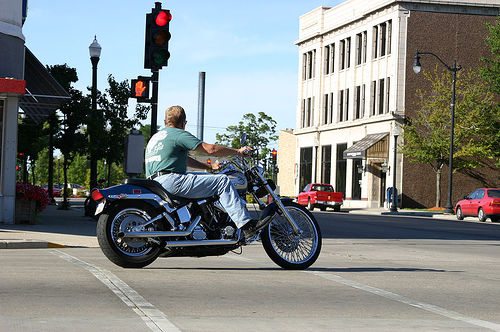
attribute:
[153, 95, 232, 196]
man — riding, without helmet, watching, driving, casting, out, enjoying, old, turned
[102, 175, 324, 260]
motorcycle — blue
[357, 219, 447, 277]
street — dark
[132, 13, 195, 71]
light — red, black, not on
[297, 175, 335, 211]
truck — red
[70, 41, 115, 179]
post — tall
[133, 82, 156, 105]
hand — up, symbol, orange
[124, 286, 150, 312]
line — white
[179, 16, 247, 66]
sky — blue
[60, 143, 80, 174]
tree — green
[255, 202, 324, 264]
tire — black, round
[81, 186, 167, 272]
tire — black, round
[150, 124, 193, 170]
shirt — green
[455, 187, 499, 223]
sedan — parked, compact